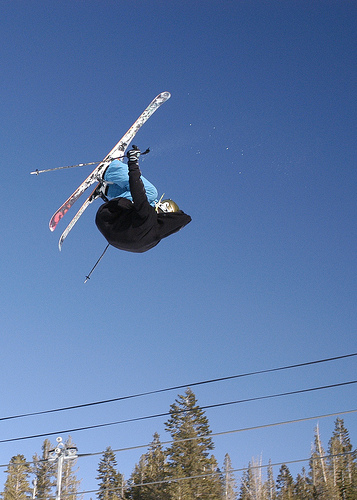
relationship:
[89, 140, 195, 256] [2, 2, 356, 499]
person in sky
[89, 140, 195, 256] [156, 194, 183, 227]
person wearing helmet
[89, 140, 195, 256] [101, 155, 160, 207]
person wearing pants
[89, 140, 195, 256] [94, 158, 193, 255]
person wearing jacket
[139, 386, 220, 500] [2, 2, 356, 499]
tree in sky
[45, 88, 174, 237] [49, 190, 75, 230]
ski has graphic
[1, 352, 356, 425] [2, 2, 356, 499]
wire going across sky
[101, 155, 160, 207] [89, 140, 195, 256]
pants worn on person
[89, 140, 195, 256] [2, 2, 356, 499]
person up in sky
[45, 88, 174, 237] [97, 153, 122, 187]
ski worn on foot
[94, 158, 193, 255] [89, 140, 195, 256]
jacket worn on person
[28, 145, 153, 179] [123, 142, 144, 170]
ski pole held in glove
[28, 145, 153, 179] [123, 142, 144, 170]
ski pole on left glove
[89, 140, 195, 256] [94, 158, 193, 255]
person wears jacket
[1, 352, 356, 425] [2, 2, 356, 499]
wire across sky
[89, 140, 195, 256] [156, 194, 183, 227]
person wears helmet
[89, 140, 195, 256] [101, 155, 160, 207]
person has pants